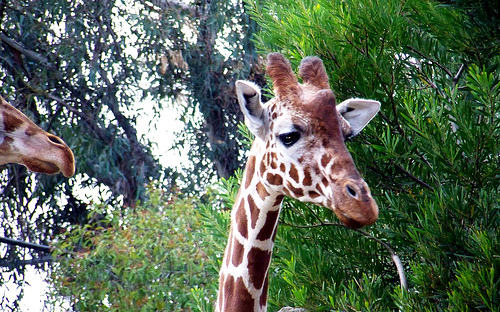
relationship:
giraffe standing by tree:
[212, 47, 379, 309] [228, 3, 496, 310]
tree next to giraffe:
[334, 25, 456, 146] [203, 26, 388, 295]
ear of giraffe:
[235, 76, 271, 127] [212, 47, 379, 309]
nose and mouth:
[339, 197, 381, 224] [327, 205, 378, 228]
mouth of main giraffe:
[327, 205, 378, 228] [212, 47, 379, 309]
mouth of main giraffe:
[327, 205, 378, 228] [170, 29, 427, 309]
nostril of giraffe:
[339, 180, 362, 202] [212, 47, 379, 309]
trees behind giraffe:
[0, 3, 499, 310] [0, 96, 77, 178]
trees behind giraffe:
[0, 3, 499, 310] [212, 47, 379, 309]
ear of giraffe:
[232, 78, 265, 126] [197, 40, 415, 308]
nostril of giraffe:
[46, 133, 63, 146] [0, 96, 77, 178]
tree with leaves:
[41, 25, 213, 253] [40, 102, 75, 139]